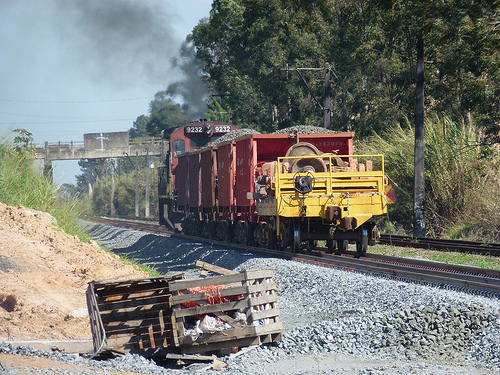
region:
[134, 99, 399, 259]
small train with it's cars filled with gravel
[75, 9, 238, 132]
smoke coming from train's smoke stack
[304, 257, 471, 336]
rocks and gravel on the side of the train tracks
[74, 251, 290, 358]
two wooden boxes left on side of train tracks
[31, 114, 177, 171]
overpass over the train tracks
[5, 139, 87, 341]
tall green grass on a small hill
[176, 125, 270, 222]
five red train cars filled with gravel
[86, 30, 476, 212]
green trees lining the side of the train tracks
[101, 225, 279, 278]
shadow of train on gravel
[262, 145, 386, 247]
small yellow train car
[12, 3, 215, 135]
Beautiful blue sky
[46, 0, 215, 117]
smoke coming from the truck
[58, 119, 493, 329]
Train tracks in use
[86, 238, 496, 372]
Rocks on the side of the tracks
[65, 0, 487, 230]
trees on the side of the train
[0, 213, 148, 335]
Pile of dirt on the side of the tracks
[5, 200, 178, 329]
The dirt is tan in color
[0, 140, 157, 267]
Grass sitting on the dirt pile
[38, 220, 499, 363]
The rocks are a light gray color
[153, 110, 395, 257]
The truck is red and yellow in color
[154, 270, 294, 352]
crate full of garbage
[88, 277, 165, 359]
empty crate on the ground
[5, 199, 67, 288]
dirt hill next to the grass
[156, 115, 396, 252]
red train car on the tracks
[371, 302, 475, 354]
rocks on the side of the tracks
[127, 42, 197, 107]
dark gray hazy smoke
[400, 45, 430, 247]
tree trunk next to the tracks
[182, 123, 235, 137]
numbers on the top of the train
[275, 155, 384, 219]
the front of the train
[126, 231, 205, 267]
shadows of the train on the ground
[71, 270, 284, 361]
wooden crates on gravel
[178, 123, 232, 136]
the numbers 9232 displayed twice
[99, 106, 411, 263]
a train on tracks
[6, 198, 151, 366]
a mound of dirt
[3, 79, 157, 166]
power lines near a bridge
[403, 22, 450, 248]
a post next to the train tracks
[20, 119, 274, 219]
a bridge in front of the train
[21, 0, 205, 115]
black smoke rising from the train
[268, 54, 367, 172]
a wooden post on the right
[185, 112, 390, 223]
a train carrying gravel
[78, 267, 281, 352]
wood crates near the tracks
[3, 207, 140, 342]
pile of brown dirt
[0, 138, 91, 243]
green grass on the dirt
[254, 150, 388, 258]
yellow part of the train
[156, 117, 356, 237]
red part of the train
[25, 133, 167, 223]
gray bridge behind the train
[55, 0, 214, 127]
black smoke coming out of the train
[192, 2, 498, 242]
trees behind the train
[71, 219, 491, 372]
gray rocks beside the tracks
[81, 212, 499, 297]
brown tracks under the train